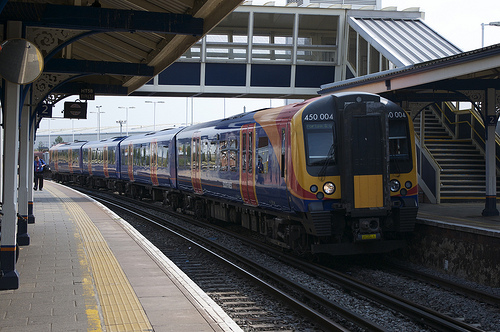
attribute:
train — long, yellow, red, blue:
[49, 87, 421, 268]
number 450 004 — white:
[300, 112, 335, 123]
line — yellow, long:
[421, 208, 500, 232]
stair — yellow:
[419, 138, 477, 147]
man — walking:
[32, 153, 48, 191]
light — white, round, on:
[320, 182, 336, 196]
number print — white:
[385, 110, 409, 120]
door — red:
[238, 121, 263, 210]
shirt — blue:
[34, 155, 50, 174]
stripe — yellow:
[35, 178, 157, 328]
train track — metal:
[42, 165, 486, 331]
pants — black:
[34, 168, 45, 194]